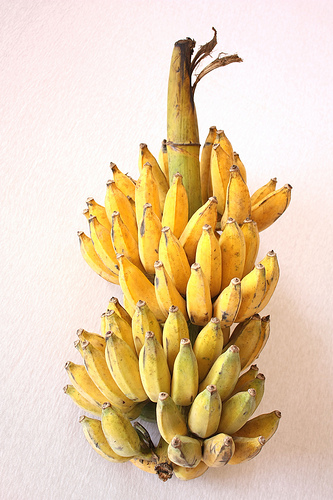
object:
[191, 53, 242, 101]
branch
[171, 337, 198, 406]
bananas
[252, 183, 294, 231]
peel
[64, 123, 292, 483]
bunch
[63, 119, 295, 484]
plantains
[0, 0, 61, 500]
wall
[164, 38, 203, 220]
stem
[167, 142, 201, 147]
ring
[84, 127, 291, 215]
upward